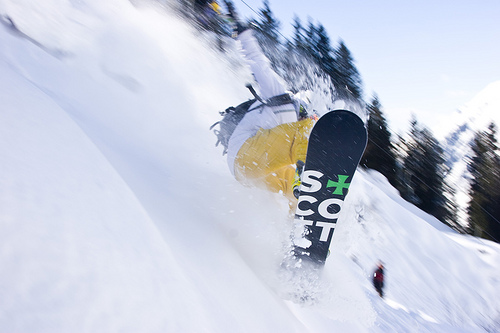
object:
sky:
[214, 0, 499, 230]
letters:
[294, 170, 324, 193]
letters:
[295, 194, 320, 218]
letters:
[288, 219, 316, 240]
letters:
[315, 219, 337, 242]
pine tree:
[462, 121, 499, 242]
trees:
[250, 0, 283, 56]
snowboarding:
[225, 25, 371, 307]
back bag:
[207, 98, 258, 157]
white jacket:
[225, 28, 308, 178]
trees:
[316, 19, 343, 88]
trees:
[283, 12, 308, 54]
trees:
[397, 120, 458, 226]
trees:
[303, 15, 318, 64]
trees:
[357, 93, 409, 199]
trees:
[332, 37, 364, 108]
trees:
[182, 0, 225, 34]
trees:
[221, 0, 247, 35]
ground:
[0, 1, 499, 332]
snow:
[0, 0, 499, 332]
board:
[275, 107, 367, 305]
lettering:
[317, 197, 348, 220]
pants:
[232, 116, 320, 225]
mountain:
[0, 0, 499, 332]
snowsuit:
[225, 27, 318, 218]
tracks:
[0, 0, 499, 331]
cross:
[326, 174, 354, 195]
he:
[224, 22, 322, 221]